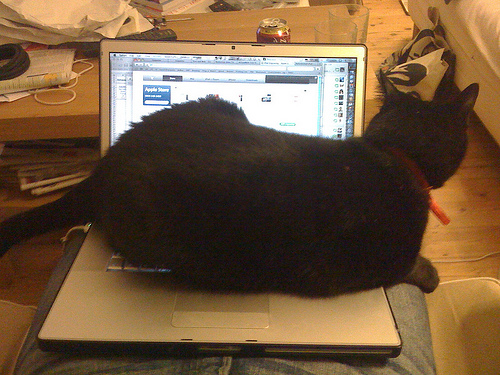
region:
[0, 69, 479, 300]
A black colored cat.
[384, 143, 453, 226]
A red cat collar.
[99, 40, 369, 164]
A lit up lap top screen.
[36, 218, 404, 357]
A silver laptop keyboard.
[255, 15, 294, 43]
A red soda can.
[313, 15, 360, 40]
A clear drinking glass.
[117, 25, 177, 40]
A black remote control.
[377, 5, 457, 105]
Black and white tote bag.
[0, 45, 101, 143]
A brown table top.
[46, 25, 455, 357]
laptop open on his lap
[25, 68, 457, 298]
cat laying on laptop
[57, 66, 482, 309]
black cat with red collar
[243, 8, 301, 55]
soda can on table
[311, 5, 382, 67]
two empty glasses on table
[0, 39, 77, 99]
newspaper on the table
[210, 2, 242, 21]
remote control on the floor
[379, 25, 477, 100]
throw pillow on the floor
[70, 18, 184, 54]
remote on the table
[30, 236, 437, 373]
man wearing blue jeans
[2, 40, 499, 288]
a cat on a laptop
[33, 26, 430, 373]
an open laptop with cat on it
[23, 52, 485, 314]
a black cat on laptop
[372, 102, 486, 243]
red collar on the cat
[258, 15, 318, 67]
a coca cola can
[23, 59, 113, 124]
a white cord on table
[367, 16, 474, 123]
a black and white bag on floor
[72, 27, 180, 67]
a black remote on table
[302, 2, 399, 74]
two glasses on the table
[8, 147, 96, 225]
a pile of papers under the table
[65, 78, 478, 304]
large black short haired cat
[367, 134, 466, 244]
red collar on neck of cat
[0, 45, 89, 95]
magazine laying on table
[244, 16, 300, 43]
red soda can sitting on table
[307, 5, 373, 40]
two drinking glasses sitting on table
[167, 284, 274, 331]
touchpad of silver laptop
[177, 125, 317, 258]
black fur on side of cat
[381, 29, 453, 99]
bag sitting on wooden floor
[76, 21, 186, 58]
black remote laying on table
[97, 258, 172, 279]
lighted laptop keyboard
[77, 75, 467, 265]
black cat laying down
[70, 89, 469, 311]
black cat laying on laptop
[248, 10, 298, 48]
soda can behind laptop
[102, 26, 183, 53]
black remote laying on table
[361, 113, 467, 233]
black cat with red collar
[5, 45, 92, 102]
magazine left folded open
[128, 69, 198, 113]
apple page on laptop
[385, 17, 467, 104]
bag in front of sofa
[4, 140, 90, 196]
stack of paper on floor